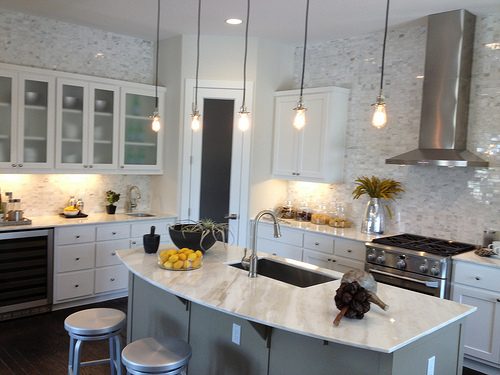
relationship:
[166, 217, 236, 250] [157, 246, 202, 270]
plant near lemons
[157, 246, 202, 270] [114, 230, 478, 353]
lemons on counter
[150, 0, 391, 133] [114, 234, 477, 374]
lights over bar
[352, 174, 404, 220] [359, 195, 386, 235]
plant in pitcher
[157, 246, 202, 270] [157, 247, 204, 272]
lemons in a bowl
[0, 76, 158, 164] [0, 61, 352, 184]
glass doors on cupboards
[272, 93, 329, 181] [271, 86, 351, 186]
two doors on cabinet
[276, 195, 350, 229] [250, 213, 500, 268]
canisters on countertop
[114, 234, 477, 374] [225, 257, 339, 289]
bar has a sink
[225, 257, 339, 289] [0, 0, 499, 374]
sink in kitchen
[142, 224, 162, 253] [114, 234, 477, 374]
mortar and pestle on bar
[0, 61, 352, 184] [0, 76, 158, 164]
cupboards have glass doors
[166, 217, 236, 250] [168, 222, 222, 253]
plant in bowl